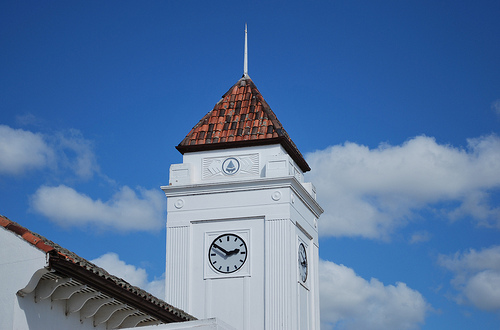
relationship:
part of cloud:
[334, 142, 370, 167] [298, 126, 496, 234]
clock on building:
[207, 231, 249, 277] [7, 21, 351, 318]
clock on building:
[207, 231, 249, 277] [3, 13, 323, 321]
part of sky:
[370, 40, 420, 109] [9, 7, 476, 317]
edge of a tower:
[288, 182, 293, 324] [152, 18, 322, 325]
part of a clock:
[292, 243, 303, 268] [290, 240, 309, 289]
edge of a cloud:
[370, 208, 403, 248] [310, 131, 483, 241]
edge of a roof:
[132, 289, 165, 309] [5, 209, 191, 318]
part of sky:
[397, 252, 433, 292] [9, 7, 476, 317]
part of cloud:
[348, 156, 406, 186] [305, 127, 494, 243]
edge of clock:
[239, 235, 249, 270] [207, 231, 249, 277]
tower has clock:
[152, 18, 322, 325] [207, 233, 247, 278]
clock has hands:
[203, 231, 248, 276] [214, 242, 243, 262]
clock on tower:
[207, 231, 249, 277] [152, 18, 322, 325]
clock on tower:
[294, 243, 312, 285] [152, 18, 322, 325]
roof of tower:
[171, 74, 312, 152] [158, 25, 321, 329]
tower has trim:
[152, 18, 322, 325] [169, 184, 287, 223]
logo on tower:
[217, 151, 246, 187] [152, 18, 322, 325]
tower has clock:
[158, 25, 321, 329] [198, 231, 248, 276]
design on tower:
[221, 156, 245, 176] [152, 22, 332, 304]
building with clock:
[6, 82, 325, 322] [206, 228, 257, 278]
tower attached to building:
[158, 25, 321, 329] [6, 82, 325, 322]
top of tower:
[240, 18, 256, 86] [158, 25, 321, 329]